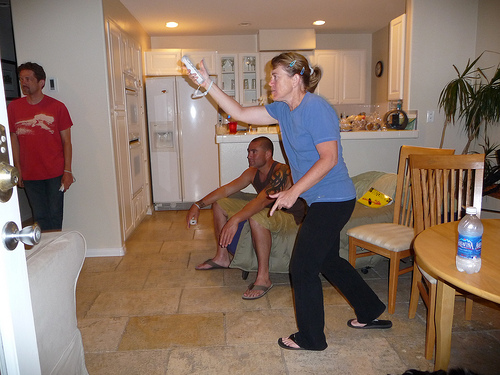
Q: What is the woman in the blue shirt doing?
A: Playing a wii game.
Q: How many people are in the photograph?
A: Three.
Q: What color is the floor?
A: Tan.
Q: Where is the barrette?
A: In the woman's hair.